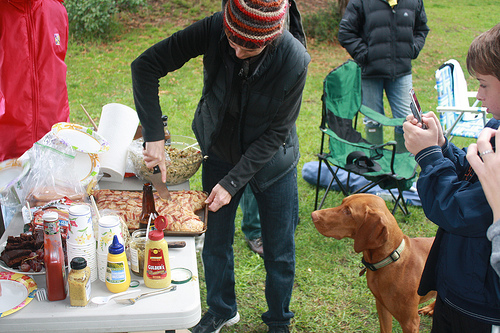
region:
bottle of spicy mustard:
[141, 213, 173, 295]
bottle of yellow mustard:
[101, 231, 135, 296]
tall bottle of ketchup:
[36, 209, 68, 304]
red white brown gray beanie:
[212, 0, 295, 47]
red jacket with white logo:
[2, 1, 71, 172]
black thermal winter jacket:
[330, 0, 437, 79]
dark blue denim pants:
[194, 163, 305, 325]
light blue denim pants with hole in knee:
[345, 65, 425, 161]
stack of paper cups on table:
[63, 202, 97, 293]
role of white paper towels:
[88, 97, 140, 187]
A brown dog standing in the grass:
[314, 190, 446, 331]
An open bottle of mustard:
[143, 216, 175, 287]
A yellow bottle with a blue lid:
[103, 234, 133, 291]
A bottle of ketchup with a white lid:
[39, 209, 71, 303]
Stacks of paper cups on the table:
[64, 202, 127, 285]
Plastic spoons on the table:
[89, 287, 174, 307]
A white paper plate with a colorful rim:
[0, 272, 40, 318]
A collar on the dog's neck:
[357, 238, 406, 280]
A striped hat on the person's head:
[219, 0, 290, 50]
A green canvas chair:
[316, 59, 425, 216]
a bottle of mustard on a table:
[106, 235, 130, 292]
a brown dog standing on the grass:
[313, 195, 436, 331]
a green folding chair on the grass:
[314, 60, 418, 218]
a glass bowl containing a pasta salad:
[131, 144, 199, 186]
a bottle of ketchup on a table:
[41, 213, 69, 299]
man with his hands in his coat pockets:
[337, 0, 429, 81]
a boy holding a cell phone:
[404, 93, 446, 158]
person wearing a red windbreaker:
[0, 3, 65, 160]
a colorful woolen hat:
[222, 1, 289, 43]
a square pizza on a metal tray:
[91, 188, 206, 235]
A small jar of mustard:
[86, 230, 136, 299]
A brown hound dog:
[311, 175, 432, 330]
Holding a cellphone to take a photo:
[387, 71, 443, 158]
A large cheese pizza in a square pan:
[87, 177, 214, 231]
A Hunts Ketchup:
[34, 200, 71, 310]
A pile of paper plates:
[15, 108, 112, 222]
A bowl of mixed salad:
[118, 135, 222, 183]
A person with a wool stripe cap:
[202, 0, 294, 70]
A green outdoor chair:
[311, 43, 431, 224]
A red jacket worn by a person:
[1, 3, 83, 140]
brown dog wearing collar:
[311, 192, 438, 332]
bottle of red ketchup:
[41, 211, 66, 301]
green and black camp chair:
[315, 58, 418, 219]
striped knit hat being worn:
[223, 0, 286, 50]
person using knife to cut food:
[131, 0, 311, 332]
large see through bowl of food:
[128, 132, 202, 187]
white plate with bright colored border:
[0, 270, 37, 318]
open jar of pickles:
[129, 228, 149, 275]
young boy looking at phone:
[401, 25, 498, 331]